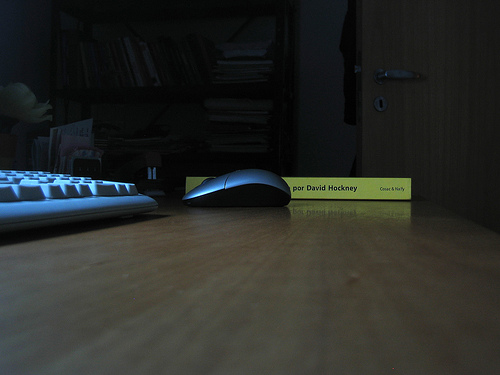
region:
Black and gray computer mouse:
[184, 169, 307, 219]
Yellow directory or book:
[185, 171, 426, 212]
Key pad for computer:
[0, 160, 165, 264]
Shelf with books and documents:
[50, 3, 289, 164]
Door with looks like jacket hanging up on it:
[340, 3, 365, 183]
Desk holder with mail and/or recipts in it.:
[35, 125, 133, 177]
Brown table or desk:
[124, 220, 497, 322]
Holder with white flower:
[0, 73, 54, 171]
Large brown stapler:
[113, 157, 175, 199]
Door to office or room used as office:
[357, 23, 472, 191]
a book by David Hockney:
[183, 168, 414, 201]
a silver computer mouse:
[178, 160, 294, 210]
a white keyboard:
[1, 165, 161, 246]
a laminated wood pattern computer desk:
[1, 185, 496, 373]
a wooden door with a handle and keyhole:
[353, 2, 498, 234]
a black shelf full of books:
[48, 0, 294, 198]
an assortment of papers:
[26, 116, 105, 187]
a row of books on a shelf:
[55, 29, 282, 91]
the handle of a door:
[369, 61, 425, 91]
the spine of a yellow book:
[184, 174, 416, 202]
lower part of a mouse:
[263, 190, 282, 205]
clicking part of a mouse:
[211, 180, 220, 186]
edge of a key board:
[83, 198, 116, 214]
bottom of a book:
[404, 177, 416, 189]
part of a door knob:
[389, 72, 412, 79]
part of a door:
[411, 123, 426, 144]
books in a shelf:
[168, 59, 230, 66]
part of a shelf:
[194, 35, 226, 87]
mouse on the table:
[160, 153, 290, 246]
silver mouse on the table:
[189, 155, 298, 215]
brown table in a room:
[145, 231, 301, 323]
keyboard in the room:
[24, 168, 149, 233]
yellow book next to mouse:
[315, 161, 415, 221]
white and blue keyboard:
[13, 163, 120, 225]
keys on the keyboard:
[12, 135, 114, 215]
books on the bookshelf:
[61, 21, 240, 100]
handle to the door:
[361, 55, 429, 113]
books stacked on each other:
[220, 31, 272, 91]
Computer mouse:
[181, 165, 294, 213]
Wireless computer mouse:
[177, 165, 294, 215]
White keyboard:
[0, 161, 157, 242]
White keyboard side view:
[0, 164, 161, 249]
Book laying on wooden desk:
[180, 165, 415, 202]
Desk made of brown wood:
[145, 218, 400, 371]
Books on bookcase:
[198, 28, 285, 165]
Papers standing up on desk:
[16, 116, 106, 176]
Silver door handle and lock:
[350, 52, 421, 122]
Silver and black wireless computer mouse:
[178, 163, 299, 218]